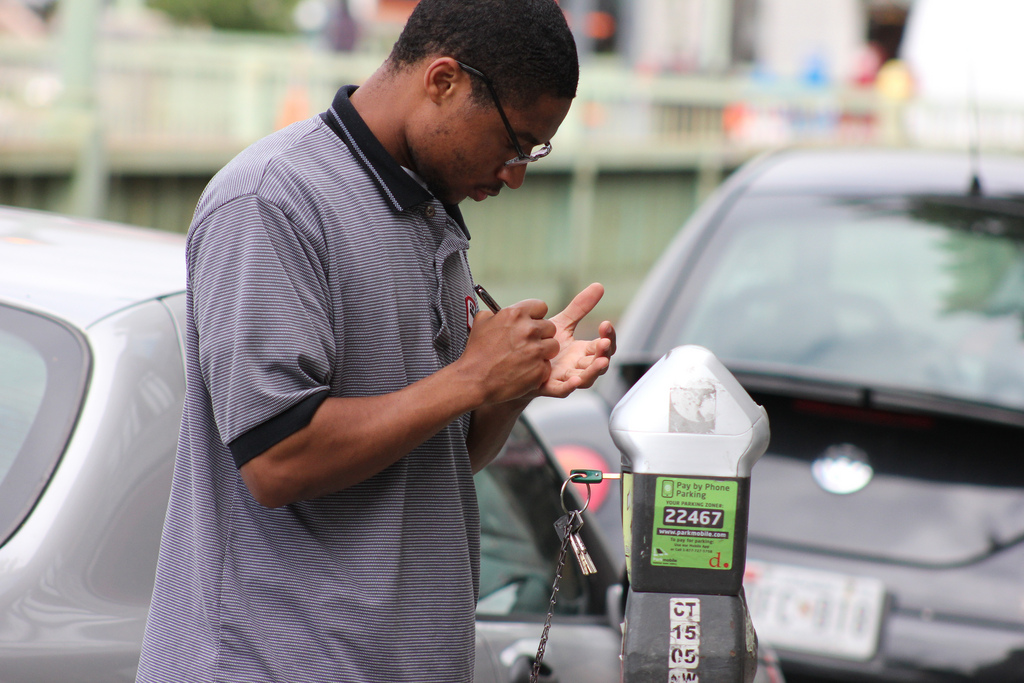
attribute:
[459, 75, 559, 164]
glasses — white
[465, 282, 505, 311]
blackpen — black